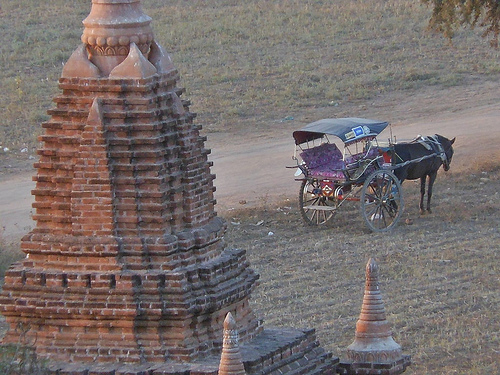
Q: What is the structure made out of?
A: Brick.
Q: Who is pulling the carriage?
A: The horse.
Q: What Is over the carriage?
A: Canopy.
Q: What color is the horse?
A: Brown.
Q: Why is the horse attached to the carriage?
A: Transportation.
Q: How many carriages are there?
A: One.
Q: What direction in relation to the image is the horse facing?
A: Right.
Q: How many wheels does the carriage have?
A: Two.